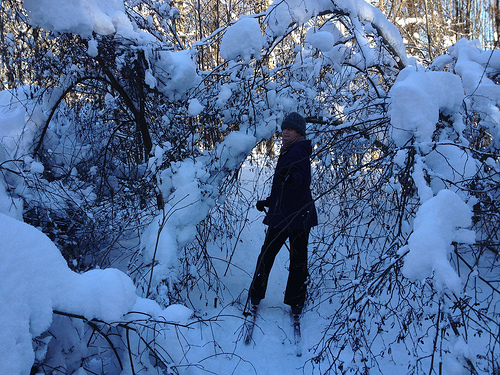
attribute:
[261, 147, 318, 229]
jacket — black, blue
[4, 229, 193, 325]
snow — on tree, white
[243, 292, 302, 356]
skis — on snow, snow-covered, black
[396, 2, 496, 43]
sky — blue, in background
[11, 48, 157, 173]
branches — brown, black, snow-covered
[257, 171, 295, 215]
gloves — black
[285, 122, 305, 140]
hair — brown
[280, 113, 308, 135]
hat — grey, wool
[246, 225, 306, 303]
pants — black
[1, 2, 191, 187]
tree — dead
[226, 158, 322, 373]
trail — snowy, snow-covered